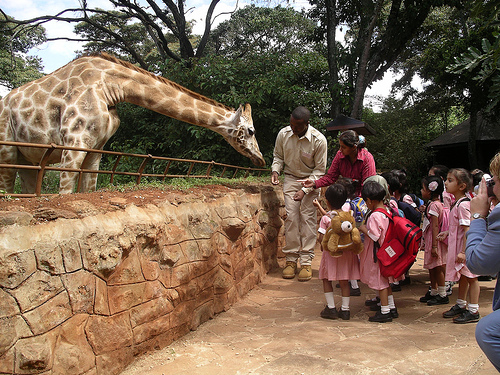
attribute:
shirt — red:
[298, 139, 379, 191]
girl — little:
[358, 180, 398, 321]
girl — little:
[420, 176, 448, 306]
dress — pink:
[441, 194, 471, 286]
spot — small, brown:
[80, 89, 98, 114]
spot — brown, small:
[57, 168, 67, 178]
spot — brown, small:
[26, 127, 50, 141]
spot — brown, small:
[229, 114, 238, 122]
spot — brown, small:
[74, 113, 78, 130]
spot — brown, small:
[215, 107, 225, 117]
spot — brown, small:
[7, 94, 21, 106]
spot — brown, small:
[214, 109, 229, 118]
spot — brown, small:
[80, 67, 98, 79]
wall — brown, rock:
[2, 176, 302, 373]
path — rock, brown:
[115, 260, 497, 371]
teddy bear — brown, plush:
[323, 209, 364, 256]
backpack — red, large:
[378, 206, 420, 287]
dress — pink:
[315, 209, 350, 285]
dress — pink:
[355, 211, 398, 288]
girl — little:
[356, 180, 415, 318]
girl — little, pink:
[410, 174, 453, 306]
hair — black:
[287, 106, 312, 125]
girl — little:
[313, 187, 363, 324]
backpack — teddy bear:
[325, 210, 364, 258]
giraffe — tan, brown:
[49, 46, 268, 166]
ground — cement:
[119, 247, 485, 372]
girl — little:
[317, 181, 363, 321]